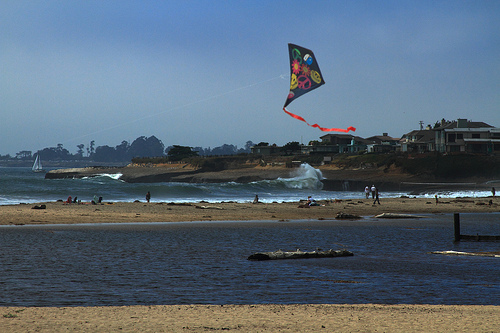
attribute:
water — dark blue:
[3, 218, 500, 304]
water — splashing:
[7, 161, 478, 198]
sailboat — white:
[28, 151, 48, 177]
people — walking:
[358, 183, 388, 210]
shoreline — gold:
[0, 186, 498, 220]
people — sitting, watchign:
[61, 193, 109, 209]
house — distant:
[318, 127, 366, 151]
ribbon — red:
[286, 107, 355, 141]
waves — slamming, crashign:
[242, 166, 338, 197]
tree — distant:
[278, 139, 305, 153]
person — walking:
[487, 183, 496, 200]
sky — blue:
[0, 4, 498, 149]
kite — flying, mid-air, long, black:
[284, 43, 324, 110]